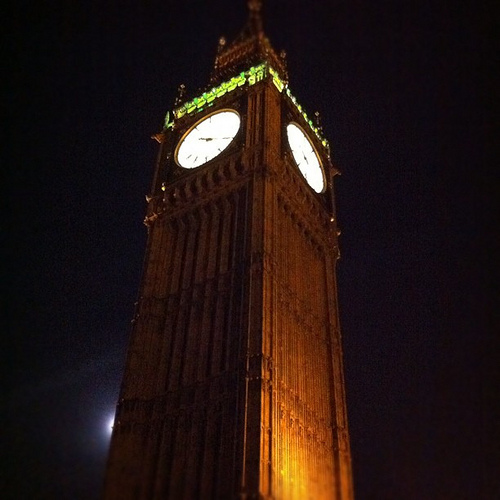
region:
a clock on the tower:
[173, 105, 243, 170]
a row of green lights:
[167, 61, 268, 118]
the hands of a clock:
[192, 133, 223, 143]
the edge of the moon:
[96, 405, 121, 441]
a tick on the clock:
[205, 110, 216, 126]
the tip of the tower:
[177, 2, 298, 95]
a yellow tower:
[102, 180, 362, 497]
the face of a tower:
[103, 175, 258, 499]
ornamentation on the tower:
[139, 150, 259, 218]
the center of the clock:
[203, 132, 211, 144]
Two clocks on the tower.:
[167, 16, 360, 240]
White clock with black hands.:
[190, 76, 267, 194]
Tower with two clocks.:
[112, 37, 430, 311]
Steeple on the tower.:
[206, 25, 325, 103]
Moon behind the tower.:
[98, 363, 154, 446]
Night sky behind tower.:
[63, 311, 428, 498]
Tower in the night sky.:
[131, 14, 421, 319]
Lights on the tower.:
[164, 60, 294, 86]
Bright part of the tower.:
[255, 399, 371, 498]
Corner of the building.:
[131, 94, 208, 219]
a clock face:
[185, 122, 228, 164]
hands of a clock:
[198, 133, 230, 142]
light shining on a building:
[269, 407, 310, 489]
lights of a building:
[230, 59, 283, 99]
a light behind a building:
[99, 419, 118, 439]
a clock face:
[282, 122, 334, 197]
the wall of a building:
[154, 251, 221, 328]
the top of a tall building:
[204, 22, 286, 60]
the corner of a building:
[238, 242, 286, 308]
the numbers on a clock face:
[177, 148, 212, 164]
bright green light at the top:
[191, 90, 242, 102]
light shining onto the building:
[269, 420, 309, 497]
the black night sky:
[369, 32, 480, 338]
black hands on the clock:
[201, 137, 219, 142]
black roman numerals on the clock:
[188, 152, 203, 164]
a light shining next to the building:
[106, 409, 113, 436]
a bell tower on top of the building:
[210, 9, 288, 70]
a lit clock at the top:
[275, 107, 350, 205]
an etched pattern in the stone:
[271, 321, 328, 379]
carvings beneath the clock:
[171, 179, 227, 196]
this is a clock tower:
[108, 204, 358, 493]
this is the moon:
[105, 402, 122, 444]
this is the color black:
[441, 313, 478, 368]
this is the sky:
[39, 229, 116, 304]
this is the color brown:
[172, 313, 227, 379]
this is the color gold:
[278, 465, 296, 479]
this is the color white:
[311, 179, 317, 183]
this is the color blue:
[91, 394, 113, 413]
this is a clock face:
[271, 108, 356, 196]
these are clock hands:
[198, 124, 240, 144]